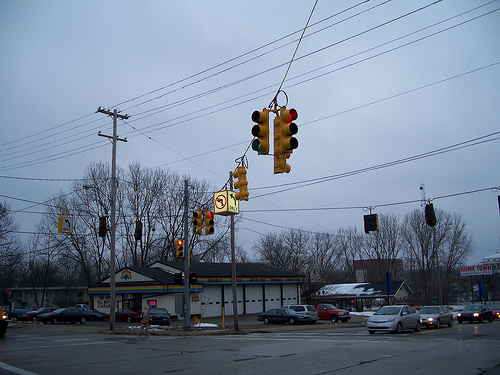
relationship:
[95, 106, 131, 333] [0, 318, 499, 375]
pole next to road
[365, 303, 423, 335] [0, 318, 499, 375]
car on road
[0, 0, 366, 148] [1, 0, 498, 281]
wire in sky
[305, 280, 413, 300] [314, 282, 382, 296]
roof has snow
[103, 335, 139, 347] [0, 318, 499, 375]
puddle on road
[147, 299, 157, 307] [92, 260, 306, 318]
sign on building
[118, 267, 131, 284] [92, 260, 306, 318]
logo on building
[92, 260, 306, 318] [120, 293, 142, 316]
building has door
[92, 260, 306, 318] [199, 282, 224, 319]
building has garage door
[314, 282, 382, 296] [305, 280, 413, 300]
snow on roof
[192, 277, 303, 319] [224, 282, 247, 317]
garage has door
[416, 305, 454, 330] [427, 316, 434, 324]
car has headlight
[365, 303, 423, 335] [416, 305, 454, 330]
car in front of car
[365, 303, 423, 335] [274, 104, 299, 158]
car at traffic light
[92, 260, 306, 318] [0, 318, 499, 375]
building near road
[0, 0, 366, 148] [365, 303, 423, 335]
wire above car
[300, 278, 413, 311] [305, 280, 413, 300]
building has roof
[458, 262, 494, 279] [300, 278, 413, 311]
sign near building